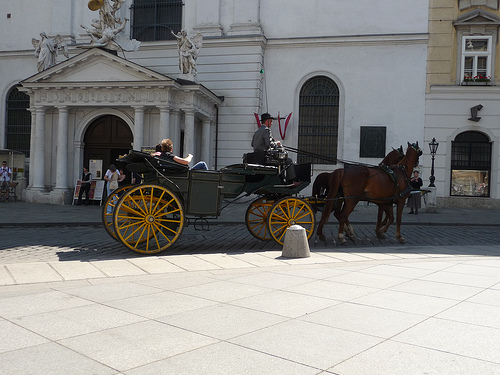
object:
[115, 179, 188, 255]
wheel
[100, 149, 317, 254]
cart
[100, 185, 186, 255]
wheels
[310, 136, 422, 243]
horse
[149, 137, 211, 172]
men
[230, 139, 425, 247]
chariot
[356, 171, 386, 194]
fur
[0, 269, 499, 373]
ground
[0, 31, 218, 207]
building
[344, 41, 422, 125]
wall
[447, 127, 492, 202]
door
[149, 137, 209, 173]
people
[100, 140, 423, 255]
carriage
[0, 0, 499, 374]
day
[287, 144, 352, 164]
reins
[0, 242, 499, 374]
street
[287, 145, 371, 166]
ropes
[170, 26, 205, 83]
statue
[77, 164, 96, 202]
people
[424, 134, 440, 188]
street light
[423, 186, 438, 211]
stand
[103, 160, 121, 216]
man